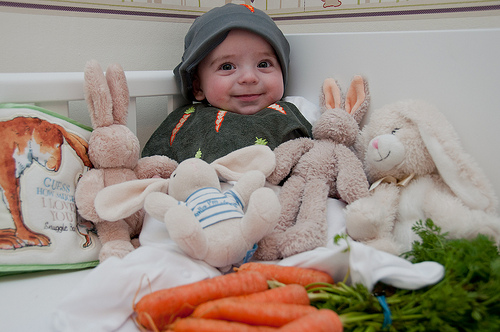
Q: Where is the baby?
A: In the middle.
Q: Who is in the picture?
A: A baby.